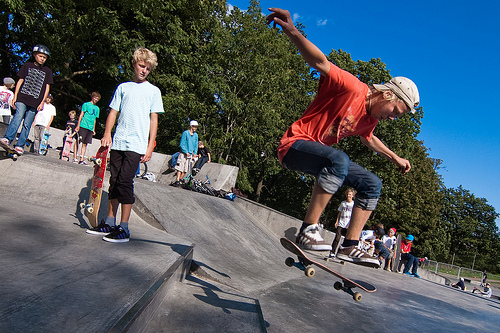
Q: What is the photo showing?
A: It is showing a skate park.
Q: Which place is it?
A: It is a skate park.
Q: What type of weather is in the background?
A: It is clear.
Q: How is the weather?
A: It is clear.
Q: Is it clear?
A: Yes, it is clear.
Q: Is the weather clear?
A: Yes, it is clear.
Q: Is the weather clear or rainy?
A: It is clear.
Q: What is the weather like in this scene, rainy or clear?
A: It is clear.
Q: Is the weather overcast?
A: No, it is clear.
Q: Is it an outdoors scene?
A: Yes, it is outdoors.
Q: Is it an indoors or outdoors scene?
A: It is outdoors.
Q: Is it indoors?
A: No, it is outdoors.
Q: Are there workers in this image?
A: No, there are no workers.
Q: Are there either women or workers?
A: No, there are no workers or women.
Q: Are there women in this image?
A: No, there are no women.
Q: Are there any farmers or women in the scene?
A: No, there are no women or farmers.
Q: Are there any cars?
A: No, there are no cars.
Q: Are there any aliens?
A: No, there are no aliens.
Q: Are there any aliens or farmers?
A: No, there are no aliens or farmers.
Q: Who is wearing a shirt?
A: The boy is wearing a shirt.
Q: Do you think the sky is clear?
A: Yes, the sky is clear.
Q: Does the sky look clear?
A: Yes, the sky is clear.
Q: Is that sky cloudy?
A: No, the sky is clear.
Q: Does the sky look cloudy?
A: No, the sky is clear.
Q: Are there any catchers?
A: No, there are no catchers.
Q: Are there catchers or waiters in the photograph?
A: No, there are no catchers or waiters.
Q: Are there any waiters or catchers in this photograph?
A: No, there are no catchers or waiters.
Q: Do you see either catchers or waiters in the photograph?
A: No, there are no catchers or waiters.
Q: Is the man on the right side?
A: Yes, the man is on the right of the image.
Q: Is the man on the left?
A: No, the man is on the right of the image.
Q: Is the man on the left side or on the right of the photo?
A: The man is on the right of the image.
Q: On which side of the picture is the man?
A: The man is on the right of the image.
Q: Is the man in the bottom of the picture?
A: Yes, the man is in the bottom of the image.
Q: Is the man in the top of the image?
A: No, the man is in the bottom of the image.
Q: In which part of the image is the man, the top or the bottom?
A: The man is in the bottom of the image.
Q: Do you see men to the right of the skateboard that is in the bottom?
A: Yes, there is a man to the right of the skateboard.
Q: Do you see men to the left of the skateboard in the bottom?
A: No, the man is to the right of the skateboard.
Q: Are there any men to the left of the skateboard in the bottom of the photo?
A: No, the man is to the right of the skateboard.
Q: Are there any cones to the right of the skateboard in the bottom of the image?
A: No, there is a man to the right of the skateboard.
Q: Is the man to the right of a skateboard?
A: Yes, the man is to the right of a skateboard.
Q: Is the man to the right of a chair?
A: No, the man is to the right of a skateboard.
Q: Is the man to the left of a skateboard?
A: No, the man is to the right of a skateboard.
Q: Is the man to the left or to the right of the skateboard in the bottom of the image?
A: The man is to the right of the skateboard.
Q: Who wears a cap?
A: The man wears a cap.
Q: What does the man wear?
A: The man wears a cap.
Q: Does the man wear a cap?
A: Yes, the man wears a cap.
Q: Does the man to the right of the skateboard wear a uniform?
A: No, the man wears a cap.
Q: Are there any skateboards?
A: Yes, there is a skateboard.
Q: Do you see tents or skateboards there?
A: Yes, there is a skateboard.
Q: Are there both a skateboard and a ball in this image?
A: No, there is a skateboard but no balls.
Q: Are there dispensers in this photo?
A: No, there are no dispensers.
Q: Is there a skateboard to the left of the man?
A: Yes, there is a skateboard to the left of the man.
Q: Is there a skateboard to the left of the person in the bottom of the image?
A: Yes, there is a skateboard to the left of the man.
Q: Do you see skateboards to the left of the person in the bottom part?
A: Yes, there is a skateboard to the left of the man.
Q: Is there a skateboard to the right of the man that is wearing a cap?
A: No, the skateboard is to the left of the man.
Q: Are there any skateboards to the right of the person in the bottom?
A: No, the skateboard is to the left of the man.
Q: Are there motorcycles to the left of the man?
A: No, there is a skateboard to the left of the man.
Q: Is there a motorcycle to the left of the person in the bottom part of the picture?
A: No, there is a skateboard to the left of the man.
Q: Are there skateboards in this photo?
A: Yes, there is a skateboard.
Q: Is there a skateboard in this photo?
A: Yes, there is a skateboard.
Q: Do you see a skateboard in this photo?
A: Yes, there is a skateboard.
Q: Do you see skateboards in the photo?
A: Yes, there is a skateboard.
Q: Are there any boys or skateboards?
A: Yes, there is a skateboard.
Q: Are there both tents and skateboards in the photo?
A: No, there is a skateboard but no tents.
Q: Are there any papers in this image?
A: No, there are no papers.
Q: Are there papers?
A: No, there are no papers.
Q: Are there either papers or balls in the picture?
A: No, there are no papers or balls.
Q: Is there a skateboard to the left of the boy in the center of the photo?
A: Yes, there is a skateboard to the left of the boy.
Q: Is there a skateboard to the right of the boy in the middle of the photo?
A: No, the skateboard is to the left of the boy.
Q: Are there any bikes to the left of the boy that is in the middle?
A: No, there is a skateboard to the left of the boy.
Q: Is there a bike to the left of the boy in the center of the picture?
A: No, there is a skateboard to the left of the boy.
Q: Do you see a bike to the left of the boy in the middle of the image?
A: No, there is a skateboard to the left of the boy.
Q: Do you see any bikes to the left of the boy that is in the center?
A: No, there is a skateboard to the left of the boy.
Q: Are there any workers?
A: No, there are no workers.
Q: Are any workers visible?
A: No, there are no workers.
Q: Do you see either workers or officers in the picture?
A: No, there are no workers or officers.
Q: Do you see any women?
A: No, there are no women.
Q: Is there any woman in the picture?
A: No, there are no women.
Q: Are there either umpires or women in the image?
A: No, there are no women or umpires.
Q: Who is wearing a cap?
A: The boy is wearing a cap.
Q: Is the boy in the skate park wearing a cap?
A: Yes, the boy is wearing a cap.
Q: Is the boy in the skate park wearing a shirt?
A: Yes, the boy is wearing a shirt.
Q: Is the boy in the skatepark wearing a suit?
A: No, the boy is wearing a shirt.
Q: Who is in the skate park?
A: The boy is in the skate park.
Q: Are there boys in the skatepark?
A: Yes, there is a boy in the skatepark.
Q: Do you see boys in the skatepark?
A: Yes, there is a boy in the skatepark.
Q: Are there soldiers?
A: No, there are no soldiers.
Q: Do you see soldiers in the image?
A: No, there are no soldiers.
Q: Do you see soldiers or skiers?
A: No, there are no soldiers or skiers.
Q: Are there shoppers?
A: No, there are no shoppers.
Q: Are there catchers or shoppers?
A: No, there are no shoppers or catchers.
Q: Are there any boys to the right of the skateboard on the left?
A: Yes, there is a boy to the right of the skateboard.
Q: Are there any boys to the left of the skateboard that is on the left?
A: No, the boy is to the right of the skateboard.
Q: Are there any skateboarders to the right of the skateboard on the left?
A: No, there is a boy to the right of the skateboard.